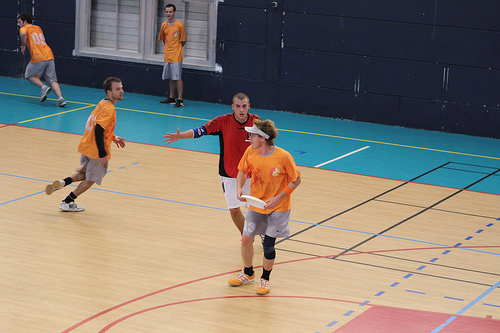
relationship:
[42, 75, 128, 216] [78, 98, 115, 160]
man wearing shirt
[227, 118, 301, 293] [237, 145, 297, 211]
man wearing shirt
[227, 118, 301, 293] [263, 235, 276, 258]
man wearing knee brace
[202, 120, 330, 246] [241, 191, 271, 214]
people play frisbee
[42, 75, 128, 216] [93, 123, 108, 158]
man has black sleeve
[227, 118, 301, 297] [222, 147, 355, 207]
man wears orange jersey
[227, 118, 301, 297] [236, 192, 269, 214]
man plays frisbee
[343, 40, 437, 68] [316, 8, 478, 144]
line on wall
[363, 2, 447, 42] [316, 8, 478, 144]
line on wall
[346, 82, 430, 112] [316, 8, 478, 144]
line on wall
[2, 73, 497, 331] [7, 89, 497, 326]
basketball court has surface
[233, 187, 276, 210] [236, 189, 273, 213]
hands on frisbee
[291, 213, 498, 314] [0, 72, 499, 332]
line on basketball court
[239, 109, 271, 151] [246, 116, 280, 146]
visor on head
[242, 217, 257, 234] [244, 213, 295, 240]
number on shorts